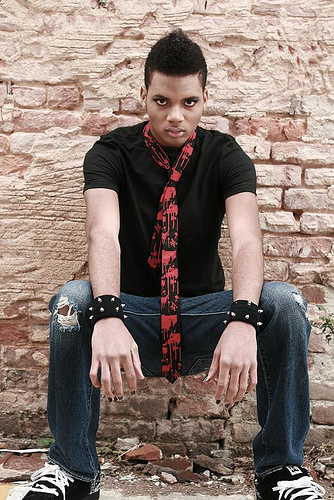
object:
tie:
[143, 116, 196, 380]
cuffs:
[223, 296, 263, 326]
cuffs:
[83, 292, 126, 323]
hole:
[50, 292, 81, 330]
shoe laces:
[23, 462, 70, 499]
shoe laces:
[270, 475, 328, 498]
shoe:
[252, 463, 324, 500]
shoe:
[7, 456, 101, 500]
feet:
[252, 456, 324, 500]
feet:
[7, 460, 101, 500]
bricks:
[115, 437, 234, 498]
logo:
[288, 460, 303, 472]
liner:
[180, 96, 196, 107]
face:
[142, 65, 206, 150]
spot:
[158, 361, 169, 374]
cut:
[149, 29, 202, 75]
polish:
[211, 399, 242, 407]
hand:
[200, 317, 263, 415]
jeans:
[46, 277, 316, 479]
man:
[6, 27, 327, 500]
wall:
[240, 33, 317, 162]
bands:
[87, 294, 128, 334]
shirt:
[81, 122, 256, 302]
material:
[48, 363, 68, 422]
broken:
[122, 429, 235, 476]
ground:
[0, 0, 334, 500]